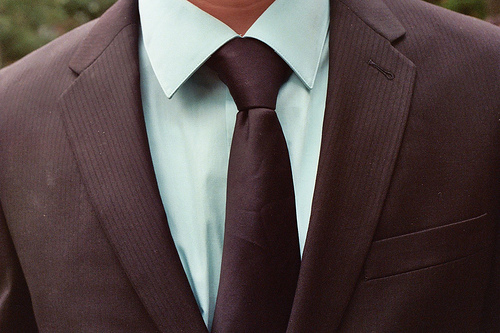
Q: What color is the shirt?
A: Brown.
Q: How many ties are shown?
A: One.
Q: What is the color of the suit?
A: Brown.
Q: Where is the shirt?
A: Under jacket.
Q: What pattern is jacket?
A: Pinstriped.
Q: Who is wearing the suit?
A: A man.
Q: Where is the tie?
A: On shirt.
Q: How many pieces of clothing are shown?
A: Three.